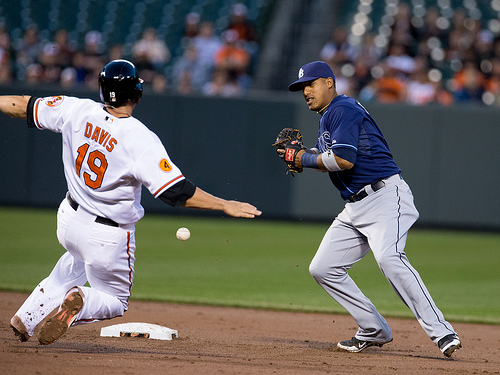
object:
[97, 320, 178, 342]
base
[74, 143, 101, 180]
team member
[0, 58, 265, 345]
baseball players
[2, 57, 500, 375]
game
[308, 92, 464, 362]
uniform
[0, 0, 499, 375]
stadium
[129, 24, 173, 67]
spectators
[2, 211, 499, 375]
ground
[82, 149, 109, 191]
numbers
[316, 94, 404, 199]
shirt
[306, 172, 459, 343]
pants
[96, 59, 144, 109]
helmet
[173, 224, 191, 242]
ball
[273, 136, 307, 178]
glove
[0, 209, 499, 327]
grass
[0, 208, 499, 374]
baseball field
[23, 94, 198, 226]
jersey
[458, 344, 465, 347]
cleat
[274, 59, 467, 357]
person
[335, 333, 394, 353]
foot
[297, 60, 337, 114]
head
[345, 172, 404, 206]
belt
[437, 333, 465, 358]
foot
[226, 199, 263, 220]
hand